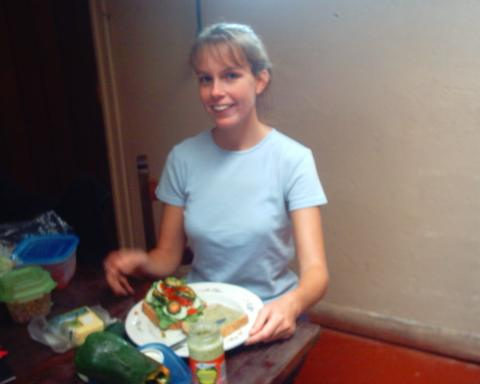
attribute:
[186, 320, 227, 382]
jar — open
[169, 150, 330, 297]
t-shirt — light blue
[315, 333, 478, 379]
floor — brown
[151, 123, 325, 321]
shirt — pale blue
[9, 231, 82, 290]
container — plastic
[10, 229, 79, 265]
lid — blue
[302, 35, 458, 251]
wall — white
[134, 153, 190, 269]
chair — wooden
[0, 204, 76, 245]
wrapper — plastic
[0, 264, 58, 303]
lid — light green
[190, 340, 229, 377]
substance — white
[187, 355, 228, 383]
lable — yellow, red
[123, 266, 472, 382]
floor — brown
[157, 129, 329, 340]
shirt — baby blue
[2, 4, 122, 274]
wall — wooden